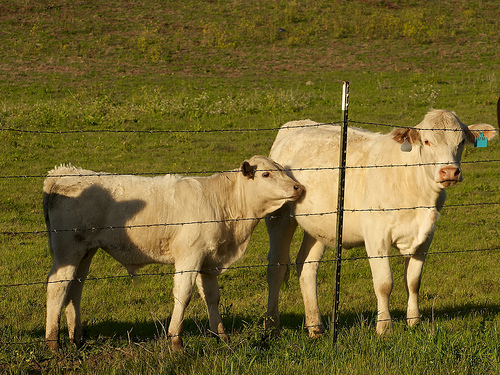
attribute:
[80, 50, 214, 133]
grass — thick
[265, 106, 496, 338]
cow — white, big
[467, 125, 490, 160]
tag — small, blue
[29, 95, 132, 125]
grass — green, thick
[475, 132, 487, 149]
tag — blue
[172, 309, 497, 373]
grass — thick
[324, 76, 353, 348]
post — green, white, metal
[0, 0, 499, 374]
grass — thick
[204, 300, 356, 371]
grass — thick, green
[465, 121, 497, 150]
tag — blue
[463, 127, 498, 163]
tag — blue